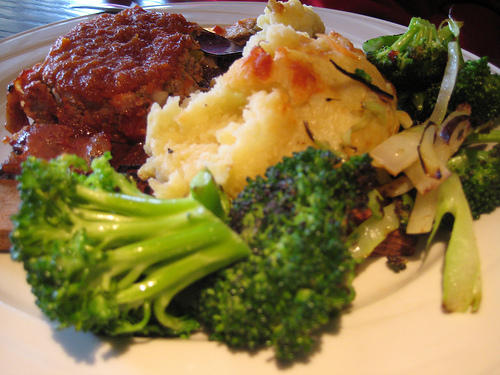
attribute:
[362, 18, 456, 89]
broccoli — cooked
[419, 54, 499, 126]
broccoli — cooked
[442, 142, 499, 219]
broccoli — cooked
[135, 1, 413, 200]
potatoes — mashed, white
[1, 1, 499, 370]
dish — round, white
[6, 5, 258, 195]
meat — mushy, red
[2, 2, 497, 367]
food — yellow, shiny, cooked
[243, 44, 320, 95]
spots — red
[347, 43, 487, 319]
vegetables — sliced, green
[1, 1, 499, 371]
plate — white, flat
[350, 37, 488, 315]
onions — fried, white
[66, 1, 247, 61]
fork — black, metallic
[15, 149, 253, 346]
broccoli — cooked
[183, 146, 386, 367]
broccoli — cooked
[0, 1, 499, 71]
table — brown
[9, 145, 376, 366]
plants — green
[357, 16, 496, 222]
plants — green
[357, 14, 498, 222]
vegetables — green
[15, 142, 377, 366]
vegetables — green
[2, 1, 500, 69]
wood — black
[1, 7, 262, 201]
beef — brown, fresh